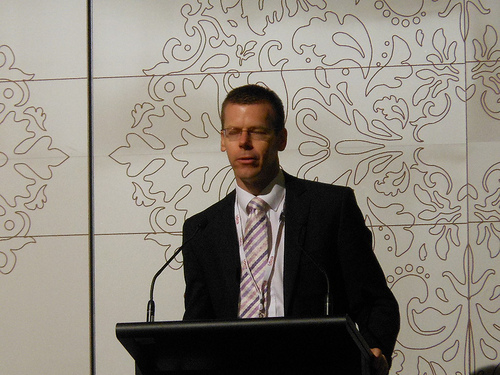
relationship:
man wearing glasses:
[182, 83, 400, 374] [221, 124, 277, 138]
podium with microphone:
[115, 312, 389, 374] [147, 216, 212, 319]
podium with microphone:
[115, 312, 389, 374] [295, 217, 333, 318]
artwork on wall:
[108, 1, 499, 374] [0, 0, 498, 375]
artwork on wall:
[0, 45, 70, 276] [0, 0, 498, 375]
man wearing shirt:
[182, 83, 400, 374] [235, 172, 285, 318]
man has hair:
[182, 83, 400, 374] [221, 85, 284, 130]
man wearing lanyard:
[182, 83, 400, 374] [234, 191, 285, 316]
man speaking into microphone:
[182, 83, 400, 374] [147, 216, 212, 319]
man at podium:
[182, 83, 400, 374] [115, 312, 389, 374]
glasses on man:
[221, 124, 277, 138] [182, 83, 400, 374]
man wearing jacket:
[182, 83, 400, 374] [182, 169, 400, 360]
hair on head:
[221, 85, 284, 130] [218, 85, 287, 194]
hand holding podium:
[371, 347, 391, 374] [115, 312, 389, 374]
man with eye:
[182, 83, 400, 374] [251, 127, 266, 136]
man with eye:
[182, 83, 400, 374] [227, 131, 240, 138]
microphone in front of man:
[147, 216, 212, 319] [182, 83, 400, 374]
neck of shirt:
[236, 176, 286, 218] [235, 172, 285, 318]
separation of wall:
[86, 1, 96, 374] [0, 0, 498, 375]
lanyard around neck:
[234, 191, 285, 316] [236, 176, 286, 218]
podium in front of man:
[115, 312, 389, 374] [182, 83, 400, 374]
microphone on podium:
[147, 216, 212, 319] [115, 312, 389, 374]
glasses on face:
[221, 124, 277, 138] [223, 102, 277, 181]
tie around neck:
[239, 198, 270, 316] [236, 176, 286, 218]